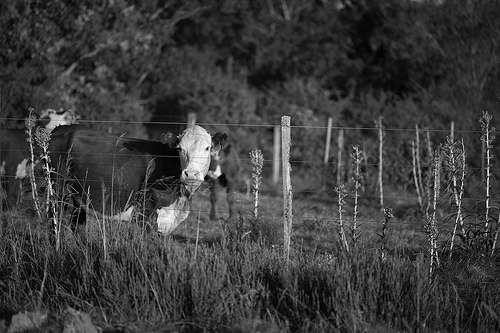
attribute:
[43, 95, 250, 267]
cow — brown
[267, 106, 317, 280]
wooden post — brown, tall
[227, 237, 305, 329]
grass — dry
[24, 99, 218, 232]
cow — white, black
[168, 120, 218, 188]
head — white, cow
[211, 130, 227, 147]
ear — black, cow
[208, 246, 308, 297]
grass — tall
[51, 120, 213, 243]
cow — standing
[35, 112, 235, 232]
cow — standing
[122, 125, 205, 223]
fence — standing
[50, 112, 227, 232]
cow — standing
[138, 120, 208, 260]
fence — standing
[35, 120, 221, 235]
cow — standing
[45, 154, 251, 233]
cow — standing, behind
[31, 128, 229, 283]
cow — behind, standing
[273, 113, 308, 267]
post — wooden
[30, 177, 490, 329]
grass — tall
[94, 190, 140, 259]
plants — coming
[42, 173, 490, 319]
grass — tall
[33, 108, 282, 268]
wires — metal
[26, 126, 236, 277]
cow — penned, in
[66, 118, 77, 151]
bone — protruding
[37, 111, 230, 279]
cow — standing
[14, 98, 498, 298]
fence — wire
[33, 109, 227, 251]
cow — brown, standing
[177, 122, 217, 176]
face — white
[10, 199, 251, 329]
bushes — big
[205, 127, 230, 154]
ear — brown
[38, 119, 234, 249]
cow — grown, adult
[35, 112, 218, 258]
cow — brown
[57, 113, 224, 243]
cow — brown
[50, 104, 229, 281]
cow — brown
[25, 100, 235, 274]
cow — brown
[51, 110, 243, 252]
cow — brown